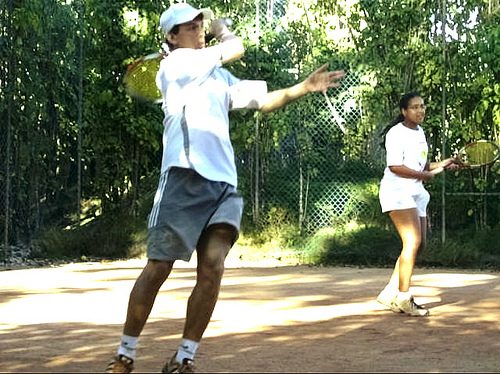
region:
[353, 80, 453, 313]
this is a person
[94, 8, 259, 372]
this is a person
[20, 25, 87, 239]
this is a tree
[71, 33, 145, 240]
this is a tree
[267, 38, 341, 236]
this is a tree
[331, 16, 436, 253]
this is a tree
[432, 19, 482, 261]
this is a tree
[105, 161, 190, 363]
a leg of a person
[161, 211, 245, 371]
a leg of a person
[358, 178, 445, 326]
a leg of a person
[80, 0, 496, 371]
Two people are playing a game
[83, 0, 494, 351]
Two people are getting some exercise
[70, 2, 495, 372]
The people are playing some tennis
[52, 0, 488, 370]
The people are on a tennis court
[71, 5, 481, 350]
The people are in a city park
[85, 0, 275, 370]
A person is wearing a hat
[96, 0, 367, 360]
A person is holding a tennis racket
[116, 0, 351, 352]
A person is wearing short pants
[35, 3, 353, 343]
A person is having a good time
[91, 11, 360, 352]
A person is enjoying their day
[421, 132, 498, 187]
tennis racket in girls hands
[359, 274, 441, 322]
pair of off white sneakers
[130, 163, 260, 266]
grey shorts with white stripes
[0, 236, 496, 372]
dirt ground in fenced in field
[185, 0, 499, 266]
tall chain link fence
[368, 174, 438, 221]
pair of white shorts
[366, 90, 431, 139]
one single black braid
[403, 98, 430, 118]
pair of eye glasses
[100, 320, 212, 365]
pair of white socks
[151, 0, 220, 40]
white baseball cap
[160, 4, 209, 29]
he is waering a hat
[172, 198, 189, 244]
the shorts are gray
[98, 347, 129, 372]
the shoes are brown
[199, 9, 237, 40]
he is holding the racket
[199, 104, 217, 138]
the shirt is white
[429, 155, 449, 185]
she is holding the racket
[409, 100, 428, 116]
sge is wearing glasses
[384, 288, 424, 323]
the shoes are white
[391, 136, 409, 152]
the shirt is white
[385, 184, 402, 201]
the shorts are white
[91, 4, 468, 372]
two people playing tennis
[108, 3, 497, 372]
a man and a woman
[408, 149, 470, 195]
both hands on the racket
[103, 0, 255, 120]
racket is behind the body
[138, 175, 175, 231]
white stripes on the side of the shorts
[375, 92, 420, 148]
black hair is pulled back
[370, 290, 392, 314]
heel is lifted off the ground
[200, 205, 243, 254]
bottom of the shorts is lifted up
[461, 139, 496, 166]
neon strings on the racket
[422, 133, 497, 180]
tennis racket